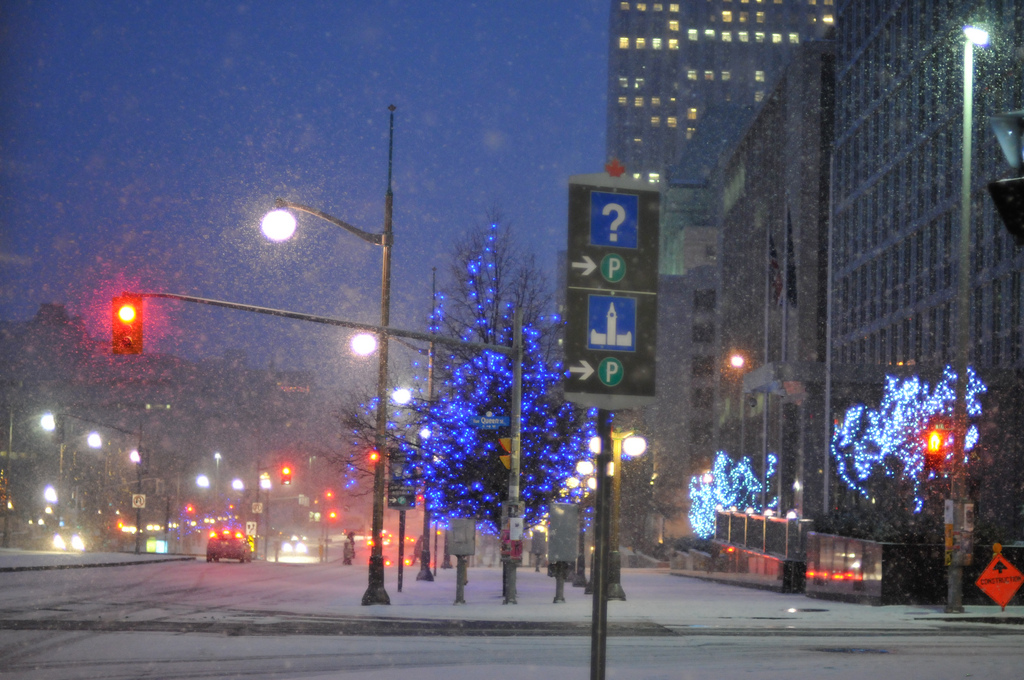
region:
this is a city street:
[55, 142, 1014, 651]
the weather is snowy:
[108, 165, 886, 513]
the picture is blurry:
[81, 157, 601, 540]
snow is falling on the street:
[76, 230, 435, 554]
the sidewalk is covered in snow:
[234, 537, 473, 607]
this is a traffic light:
[70, 253, 248, 355]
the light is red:
[58, 253, 280, 408]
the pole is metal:
[160, 239, 619, 516]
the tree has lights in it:
[427, 288, 611, 542]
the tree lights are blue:
[424, 338, 690, 583]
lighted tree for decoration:
[816, 361, 924, 521]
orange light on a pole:
[918, 416, 960, 474]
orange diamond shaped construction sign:
[977, 537, 1019, 615]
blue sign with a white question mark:
[588, 196, 637, 254]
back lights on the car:
[207, 518, 245, 548]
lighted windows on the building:
[608, 10, 809, 56]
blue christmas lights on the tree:
[428, 377, 479, 529]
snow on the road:
[196, 597, 315, 656]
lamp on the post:
[949, 16, 1000, 86]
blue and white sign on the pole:
[473, 402, 515, 440]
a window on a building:
[612, 33, 629, 52]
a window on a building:
[645, 30, 658, 53]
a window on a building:
[662, 38, 679, 55]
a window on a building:
[667, 11, 678, 30]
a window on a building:
[683, 30, 691, 38]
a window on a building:
[700, 23, 710, 39]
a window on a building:
[713, 30, 736, 41]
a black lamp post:
[269, 203, 390, 600]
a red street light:
[117, 291, 149, 350]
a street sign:
[568, 177, 648, 665]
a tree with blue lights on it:
[373, 239, 593, 544]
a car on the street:
[206, 519, 257, 554]